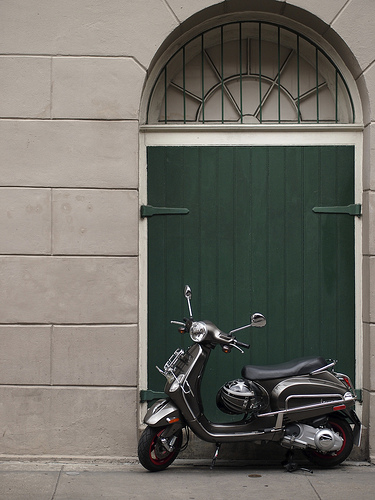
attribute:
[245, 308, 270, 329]
mirror — chrome plated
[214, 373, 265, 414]
helmet — black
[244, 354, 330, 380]
seat — soft, black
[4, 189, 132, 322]
bricks — light grey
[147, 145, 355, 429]
door — wooden, green, closed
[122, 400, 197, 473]
wheel — small, black